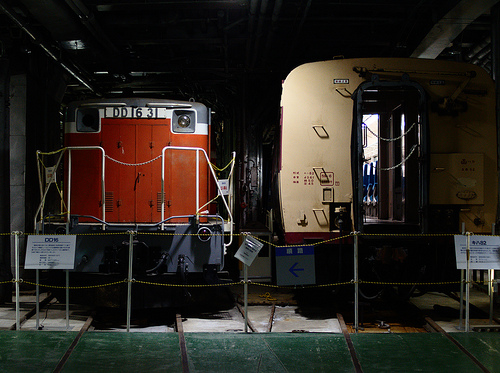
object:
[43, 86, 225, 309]
train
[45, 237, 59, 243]
lettering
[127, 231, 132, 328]
metal posts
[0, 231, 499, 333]
fence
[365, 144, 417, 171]
chain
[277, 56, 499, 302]
train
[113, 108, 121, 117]
letters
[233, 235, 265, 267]
paper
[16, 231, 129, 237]
chain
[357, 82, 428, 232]
doorway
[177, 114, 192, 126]
light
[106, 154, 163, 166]
chain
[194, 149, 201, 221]
post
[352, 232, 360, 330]
metal rail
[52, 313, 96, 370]
track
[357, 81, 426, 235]
door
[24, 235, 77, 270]
shaped sign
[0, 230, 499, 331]
chain railing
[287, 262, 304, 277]
blue arrow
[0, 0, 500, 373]
gray background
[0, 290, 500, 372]
floor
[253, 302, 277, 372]
tracks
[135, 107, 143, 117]
number